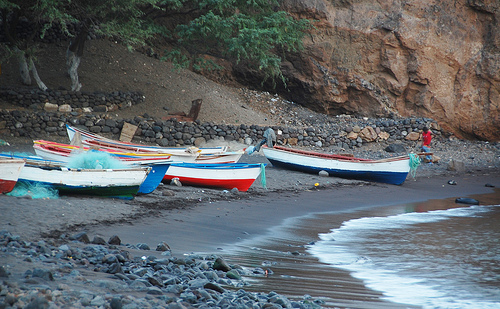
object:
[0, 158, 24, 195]
boats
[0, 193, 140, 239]
sand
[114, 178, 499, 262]
shore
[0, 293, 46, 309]
rocks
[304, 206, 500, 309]
foam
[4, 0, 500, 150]
wall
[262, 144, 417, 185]
boat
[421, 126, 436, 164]
person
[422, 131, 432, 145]
shirt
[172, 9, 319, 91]
leaves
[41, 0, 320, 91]
tree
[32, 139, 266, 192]
boat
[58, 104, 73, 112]
rocks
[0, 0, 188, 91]
trees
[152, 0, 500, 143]
rock cliff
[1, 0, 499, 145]
background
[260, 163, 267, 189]
fabric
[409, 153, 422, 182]
string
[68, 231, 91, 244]
rock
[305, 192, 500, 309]
water